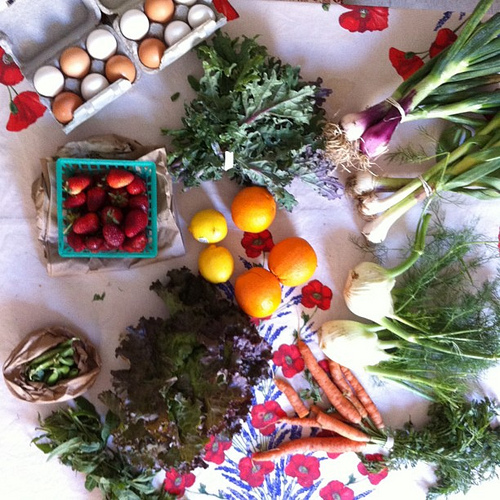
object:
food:
[2, 2, 492, 491]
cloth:
[1, 5, 500, 479]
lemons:
[196, 242, 235, 286]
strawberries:
[122, 206, 149, 238]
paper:
[34, 132, 167, 158]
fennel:
[308, 316, 499, 407]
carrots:
[249, 435, 363, 464]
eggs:
[49, 90, 86, 125]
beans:
[26, 352, 58, 380]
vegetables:
[159, 27, 334, 212]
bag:
[0, 322, 105, 405]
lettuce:
[102, 268, 272, 456]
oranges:
[232, 264, 283, 321]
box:
[55, 158, 159, 259]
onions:
[320, 0, 483, 173]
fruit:
[265, 235, 319, 289]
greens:
[29, 398, 161, 499]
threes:
[229, 183, 319, 320]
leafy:
[391, 397, 500, 499]